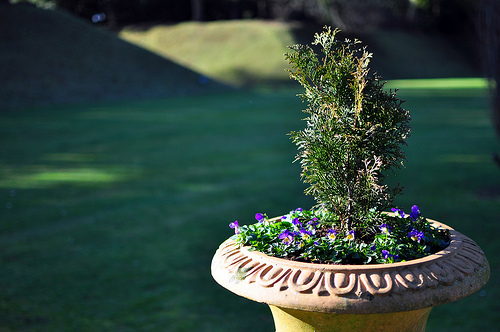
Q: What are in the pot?
A: Flowers.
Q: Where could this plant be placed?
A: On a housefront.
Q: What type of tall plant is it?
A: Evergreen.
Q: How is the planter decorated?
A: In cement.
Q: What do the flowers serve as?
A: A border.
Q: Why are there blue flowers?
A: For color.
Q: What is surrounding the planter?
A: Grass.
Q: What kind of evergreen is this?
A: Pine.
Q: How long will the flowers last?
A: Until fall.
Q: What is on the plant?
A: Little purple flowers.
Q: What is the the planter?
A: A plant.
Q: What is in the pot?
A: Blue color flowers with the plant.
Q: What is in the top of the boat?
A: Blue color flowers with the plant.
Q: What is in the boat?
A: Blue color flowers with the plant.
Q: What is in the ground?
A: Shadow of the trees.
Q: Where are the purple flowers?
A: In the plant holder.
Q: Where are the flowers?
A: In a pot holder.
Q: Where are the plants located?
A: In the center of the pot holder.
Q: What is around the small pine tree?
A: Purple flowers with green leaves.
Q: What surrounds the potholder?
A: A green grass area.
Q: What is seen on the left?
A: A slanted hill.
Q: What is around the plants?
A: A pot holder with a design on the top.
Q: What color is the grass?
A: Green.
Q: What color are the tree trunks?
A: Brown.